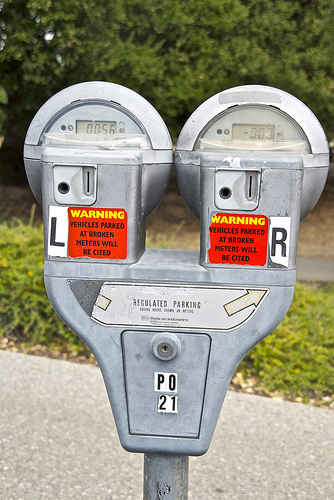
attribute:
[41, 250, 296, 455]
container — locked, for coins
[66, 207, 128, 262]
sticker — red, warning label, yellow, black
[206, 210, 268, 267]
sticker — red, black, yellow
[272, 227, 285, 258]
r — black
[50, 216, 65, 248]
l — black, large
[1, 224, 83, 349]
grass — green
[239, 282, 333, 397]
grass — green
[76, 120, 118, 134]
display — digital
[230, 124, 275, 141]
display — digital, 0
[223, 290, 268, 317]
arrow — outlined, pontimg right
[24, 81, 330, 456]
double meter — silver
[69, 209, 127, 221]
word — warning, yellow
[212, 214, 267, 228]
word — warning, yellow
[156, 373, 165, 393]
letter — black, p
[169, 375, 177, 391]
letter — black, o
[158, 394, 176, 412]
number — black, 21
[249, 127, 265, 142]
digits — 000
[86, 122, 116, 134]
digits — 0056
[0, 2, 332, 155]
trees — leafy, tall, green